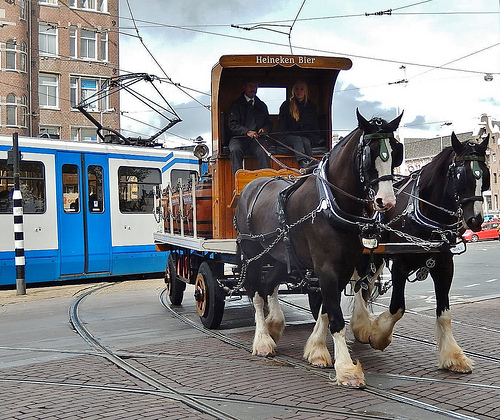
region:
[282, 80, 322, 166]
blonde woman in horse carriage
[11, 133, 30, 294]
black and white striped pole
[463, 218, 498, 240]
red car on the right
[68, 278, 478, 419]
curved railroad tracks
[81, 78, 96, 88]
light blue something in the window of the building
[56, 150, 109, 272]
blue doors on public transit system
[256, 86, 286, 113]
window in the back of the carriage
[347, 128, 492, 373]
smaller Clydesdale pulling the carriage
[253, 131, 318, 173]
two reins to direct the horses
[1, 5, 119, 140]
part of large red brick building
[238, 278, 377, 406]
white fur on a horse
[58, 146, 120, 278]
blue train doors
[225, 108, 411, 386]
a brown and white horse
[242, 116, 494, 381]
two horses pulling a carriage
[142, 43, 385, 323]
a carriage with two people in it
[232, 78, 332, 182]
two people inside a carriage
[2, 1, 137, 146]
brick building in the sky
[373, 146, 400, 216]
white skin on a horse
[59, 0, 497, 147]
cables in the sky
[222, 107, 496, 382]
Horses pulling the wagon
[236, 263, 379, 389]
The horse has white on its legs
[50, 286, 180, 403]
Track on the pavement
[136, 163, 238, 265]
The wagon is surrounded in wood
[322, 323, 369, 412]
The horse has hairy feet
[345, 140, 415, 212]
Bridle on horses face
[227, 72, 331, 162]
Woman and man sitting in seat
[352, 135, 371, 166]
Horse is wearing blinders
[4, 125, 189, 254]
Blue train beside sidewalk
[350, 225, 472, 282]
Yoke in between the horses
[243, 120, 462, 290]
the horses are brown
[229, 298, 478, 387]
horse's hooves are white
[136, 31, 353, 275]
horse carriage is orange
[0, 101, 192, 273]
blue and white train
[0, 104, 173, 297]
train is behind horses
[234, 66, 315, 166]
people sitting in carriage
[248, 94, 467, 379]
the horses are walking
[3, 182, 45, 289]
sign pole is striped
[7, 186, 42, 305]
sign pole is black and white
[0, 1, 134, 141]
brown building behind train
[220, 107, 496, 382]
Two brown horses side by side.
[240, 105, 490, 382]
Two brown and white horses.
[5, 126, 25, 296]
Poles with black and white stripes.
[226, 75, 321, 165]
Two people in horse carriage.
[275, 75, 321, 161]
A woman riding in the horse carriage.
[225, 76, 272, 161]
A man riding in the horse carriage.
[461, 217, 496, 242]
Red car in street.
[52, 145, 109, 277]
Two matching blue trolley doors.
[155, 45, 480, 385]
Brown carriage being led by horses.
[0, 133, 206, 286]
Blue and white trolley.